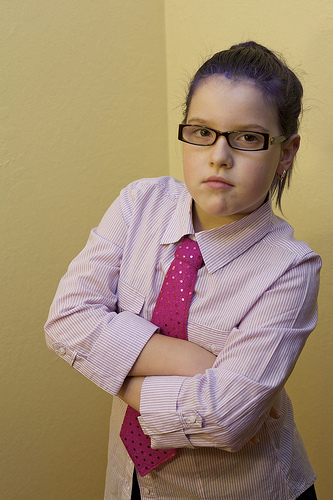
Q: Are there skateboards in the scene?
A: No, there are no skateboards.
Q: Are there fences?
A: No, there are no fences.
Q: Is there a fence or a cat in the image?
A: No, there are no fences or cats.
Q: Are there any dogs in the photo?
A: No, there are no dogs.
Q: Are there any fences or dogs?
A: No, there are no dogs or fences.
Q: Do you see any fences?
A: No, there are no fences.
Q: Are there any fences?
A: No, there are no fences.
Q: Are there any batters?
A: No, there are no batters.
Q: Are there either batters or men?
A: No, there are no batters or men.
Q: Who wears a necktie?
A: The girl wears a necktie.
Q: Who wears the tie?
A: The girl wears a necktie.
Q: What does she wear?
A: The girl wears a tie.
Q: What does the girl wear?
A: The girl wears a tie.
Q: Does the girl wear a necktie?
A: Yes, the girl wears a necktie.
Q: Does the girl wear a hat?
A: No, the girl wears a necktie.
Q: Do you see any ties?
A: Yes, there is a tie.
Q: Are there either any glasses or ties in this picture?
A: Yes, there is a tie.